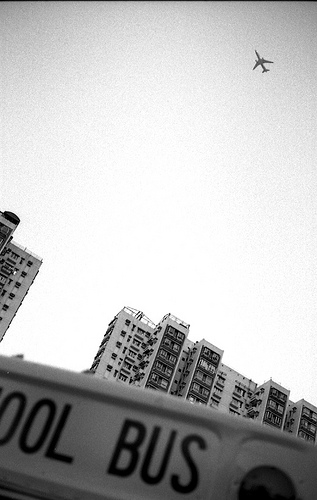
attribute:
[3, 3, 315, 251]
overcast sky — grey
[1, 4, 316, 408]
sky — grey, overcast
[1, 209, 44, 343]
building — light-colored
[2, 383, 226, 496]
letter — black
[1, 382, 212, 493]
letters — black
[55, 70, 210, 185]
sky — bright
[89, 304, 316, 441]
building — storey, light-colored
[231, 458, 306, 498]
light — circular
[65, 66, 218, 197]
skies — gray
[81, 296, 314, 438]
buildings — tall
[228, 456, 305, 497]
light — dark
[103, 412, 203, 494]
letters — black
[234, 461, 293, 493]
light — dark  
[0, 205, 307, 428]
building — tall 